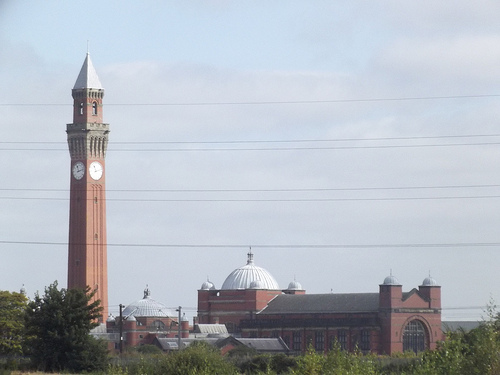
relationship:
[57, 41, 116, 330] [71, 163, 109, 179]
tower has clock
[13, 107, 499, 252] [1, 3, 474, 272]
powerlines in sky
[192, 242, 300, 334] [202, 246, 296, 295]
building has white dome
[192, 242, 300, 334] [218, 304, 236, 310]
building has brick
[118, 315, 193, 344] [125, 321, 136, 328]
building has brick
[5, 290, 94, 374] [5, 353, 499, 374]
trees on ground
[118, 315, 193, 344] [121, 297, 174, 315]
building with white dome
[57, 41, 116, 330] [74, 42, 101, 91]
tower has point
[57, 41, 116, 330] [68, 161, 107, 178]
tower has two clocks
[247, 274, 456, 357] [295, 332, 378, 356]
building has windows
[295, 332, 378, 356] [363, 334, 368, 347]
windows have bars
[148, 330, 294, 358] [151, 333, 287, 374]
roof of building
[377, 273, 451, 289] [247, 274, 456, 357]
small domes on building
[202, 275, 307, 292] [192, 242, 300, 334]
small domes on building